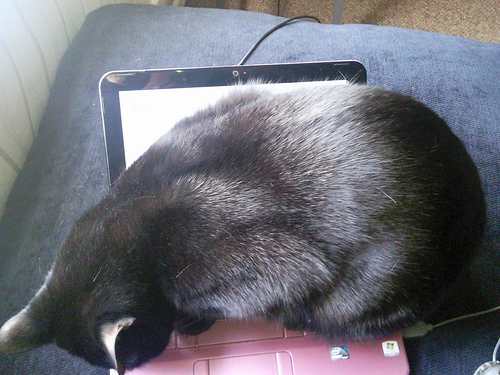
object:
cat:
[0, 78, 486, 375]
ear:
[93, 314, 141, 375]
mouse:
[193, 350, 291, 375]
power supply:
[236, 16, 319, 68]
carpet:
[0, 2, 499, 375]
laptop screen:
[114, 76, 350, 173]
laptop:
[96, 59, 409, 375]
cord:
[400, 304, 500, 338]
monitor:
[101, 61, 369, 188]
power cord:
[238, 15, 320, 66]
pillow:
[0, 4, 498, 375]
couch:
[2, 5, 499, 375]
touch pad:
[195, 351, 290, 375]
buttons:
[274, 353, 290, 375]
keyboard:
[111, 276, 410, 375]